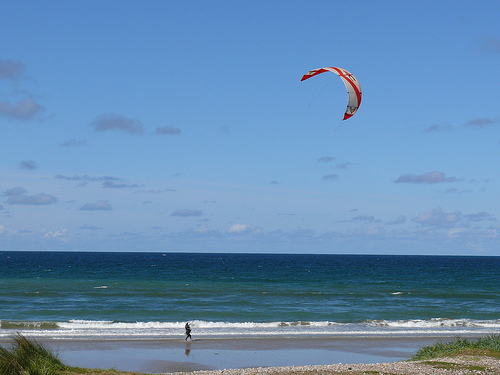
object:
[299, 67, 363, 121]
kite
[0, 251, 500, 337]
water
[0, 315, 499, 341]
waves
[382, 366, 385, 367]
gravel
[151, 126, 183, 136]
cloud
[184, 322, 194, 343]
person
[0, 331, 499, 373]
beach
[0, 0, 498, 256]
sky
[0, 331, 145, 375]
grass